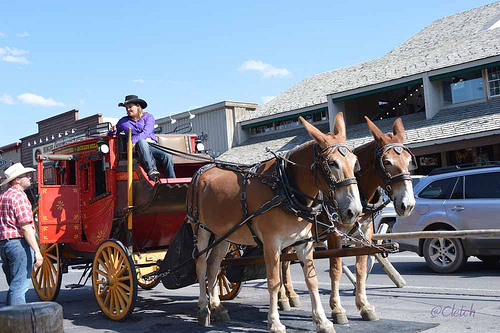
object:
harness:
[335, 177, 359, 190]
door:
[35, 153, 87, 244]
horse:
[185, 110, 362, 331]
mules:
[215, 159, 262, 184]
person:
[0, 160, 46, 313]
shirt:
[0, 185, 36, 244]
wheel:
[90, 238, 141, 322]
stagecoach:
[28, 110, 419, 333]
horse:
[274, 116, 413, 325]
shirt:
[115, 113, 162, 148]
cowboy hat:
[0, 160, 37, 188]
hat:
[118, 94, 148, 109]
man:
[103, 94, 178, 181]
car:
[388, 160, 500, 274]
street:
[1, 249, 500, 333]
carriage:
[32, 110, 416, 331]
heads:
[296, 110, 363, 227]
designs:
[56, 197, 72, 212]